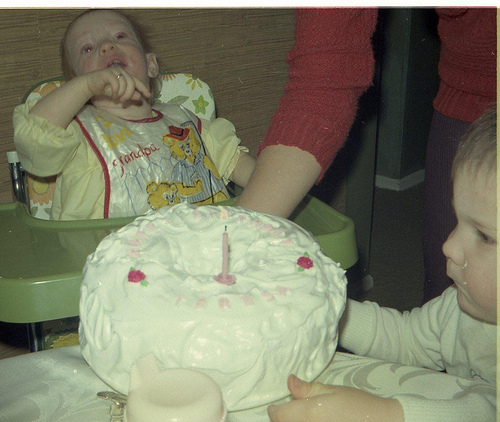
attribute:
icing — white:
[81, 203, 346, 406]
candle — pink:
[218, 232, 234, 280]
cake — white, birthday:
[83, 193, 353, 405]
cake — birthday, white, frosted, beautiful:
[75, 199, 351, 416]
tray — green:
[9, 168, 375, 355]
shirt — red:
[276, 15, 495, 160]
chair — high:
[0, 178, 363, 358]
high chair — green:
[2, 8, 372, 347]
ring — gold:
[115, 68, 125, 80]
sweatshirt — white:
[332, 278, 484, 408]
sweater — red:
[250, 8, 485, 188]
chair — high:
[7, 83, 351, 348]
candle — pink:
[216, 222, 240, 293]